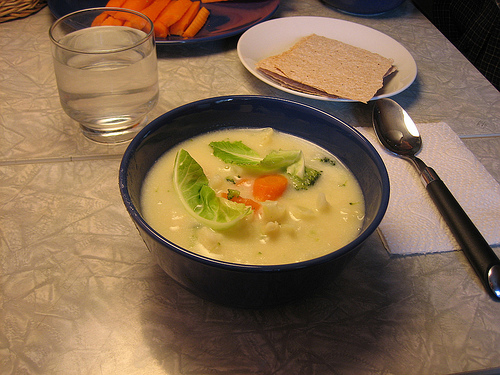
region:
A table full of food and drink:
[2, 2, 495, 371]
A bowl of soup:
[117, 94, 391, 308]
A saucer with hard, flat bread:
[235, 12, 416, 100]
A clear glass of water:
[45, 5, 155, 140]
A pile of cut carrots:
[90, 0, 210, 36]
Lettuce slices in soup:
[170, 136, 320, 226]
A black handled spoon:
[370, 96, 495, 296]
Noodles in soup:
[260, 191, 331, 237]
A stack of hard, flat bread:
[257, 32, 398, 103]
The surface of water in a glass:
[52, 26, 154, 69]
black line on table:
[68, 228, 132, 243]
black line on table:
[82, 213, 97, 231]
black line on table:
[80, 252, 147, 273]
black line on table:
[107, 245, 126, 262]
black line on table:
[1, 266, 52, 281]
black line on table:
[8, 278, 55, 305]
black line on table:
[169, 339, 186, 373]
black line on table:
[1, 118, 29, 138]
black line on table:
[4, 136, 26, 161]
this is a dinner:
[2, 23, 463, 348]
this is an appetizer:
[141, 128, 386, 328]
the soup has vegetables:
[151, 133, 296, 233]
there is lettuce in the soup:
[152, 140, 253, 242]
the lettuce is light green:
[165, 135, 265, 246]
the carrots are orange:
[232, 163, 285, 220]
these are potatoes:
[245, 193, 392, 278]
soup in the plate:
[110, 111, 359, 298]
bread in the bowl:
[262, 8, 399, 108]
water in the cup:
[43, 27, 153, 122]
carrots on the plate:
[127, 0, 195, 40]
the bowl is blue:
[297, 130, 333, 155]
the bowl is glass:
[220, 98, 277, 121]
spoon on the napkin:
[366, 78, 495, 270]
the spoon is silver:
[390, 115, 422, 168]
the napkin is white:
[385, 210, 437, 265]